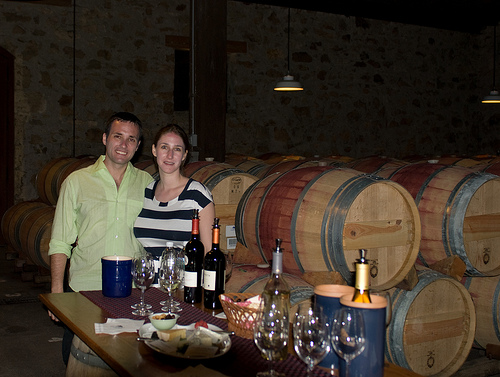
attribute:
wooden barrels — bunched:
[222, 158, 446, 280]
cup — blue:
[100, 252, 136, 299]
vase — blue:
[102, 253, 130, 296]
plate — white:
[137, 308, 225, 361]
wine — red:
[200, 215, 232, 310]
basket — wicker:
[216, 289, 269, 339]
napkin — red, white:
[217, 291, 264, 322]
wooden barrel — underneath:
[237, 163, 405, 308]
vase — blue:
[75, 247, 134, 302]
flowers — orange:
[149, 297, 251, 356]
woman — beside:
[133, 123, 216, 299]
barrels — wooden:
[209, 152, 497, 264]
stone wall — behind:
[297, 33, 446, 150]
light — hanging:
[264, 6, 316, 96]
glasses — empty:
[330, 310, 361, 369]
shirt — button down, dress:
[40, 155, 157, 289]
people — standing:
[60, 117, 222, 284]